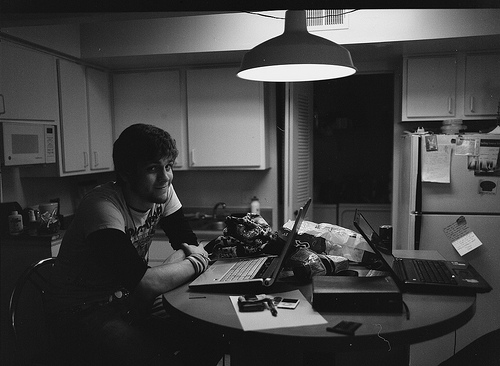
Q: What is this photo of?
A: A kitchen.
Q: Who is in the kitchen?
A: A man.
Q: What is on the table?
A: Laptops.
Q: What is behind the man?
A: A microwave.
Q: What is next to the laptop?
A: A paper.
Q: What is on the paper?
A: A ipad.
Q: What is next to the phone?
A: A pen.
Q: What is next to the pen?
A: A wallet.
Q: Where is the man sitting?
A: Table.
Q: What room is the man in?
A: Kitchen.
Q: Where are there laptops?
A: Table.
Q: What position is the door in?
A: Open.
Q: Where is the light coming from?
A: Lamp.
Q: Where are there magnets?
A: Refrigerator.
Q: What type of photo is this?
A: Black and white.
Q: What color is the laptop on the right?
A: Black.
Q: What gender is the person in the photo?
A: Male.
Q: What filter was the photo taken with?
A: Black and white.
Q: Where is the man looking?
A: At the camera.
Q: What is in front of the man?
A: A laptop.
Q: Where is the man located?
A: A kitchen.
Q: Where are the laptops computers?
A: On the table.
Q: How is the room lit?
A: With a ceiling lamp.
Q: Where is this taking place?
A: In a kitchen.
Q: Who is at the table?
A: A man.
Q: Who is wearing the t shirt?
A: The man at the table.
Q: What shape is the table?
A: Round.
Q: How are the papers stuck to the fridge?
A: With magnets.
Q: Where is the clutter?
A: On the kitchen table.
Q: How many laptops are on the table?
A: Two.